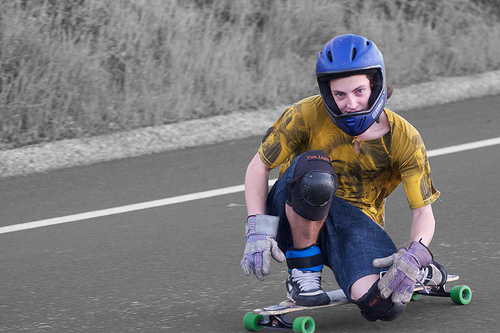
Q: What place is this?
A: It is a road.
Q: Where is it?
A: This is at the road.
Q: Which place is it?
A: It is a road.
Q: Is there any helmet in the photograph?
A: Yes, there is a helmet.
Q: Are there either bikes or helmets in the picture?
A: Yes, there is a helmet.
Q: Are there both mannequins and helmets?
A: No, there is a helmet but no mannequins.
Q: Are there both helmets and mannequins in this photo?
A: No, there is a helmet but no mannequins.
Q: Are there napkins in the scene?
A: No, there are no napkins.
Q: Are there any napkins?
A: No, there are no napkins.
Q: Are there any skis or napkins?
A: No, there are no napkins or skis.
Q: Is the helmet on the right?
A: Yes, the helmet is on the right of the image.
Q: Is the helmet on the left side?
A: No, the helmet is on the right of the image.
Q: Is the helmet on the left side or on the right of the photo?
A: The helmet is on the right of the image.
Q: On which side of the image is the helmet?
A: The helmet is on the right of the image.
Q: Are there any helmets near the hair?
A: Yes, there is a helmet near the hair.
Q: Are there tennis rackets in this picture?
A: No, there are no tennis rackets.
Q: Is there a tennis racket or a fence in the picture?
A: No, there are no rackets or fences.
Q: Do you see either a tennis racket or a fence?
A: No, there are no rackets or fences.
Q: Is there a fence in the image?
A: No, there are no fences.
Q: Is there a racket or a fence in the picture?
A: No, there are no fences or rackets.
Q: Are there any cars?
A: No, there are no cars.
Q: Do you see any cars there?
A: No, there are no cars.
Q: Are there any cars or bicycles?
A: No, there are no cars or bicycles.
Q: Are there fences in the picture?
A: No, there are no fences.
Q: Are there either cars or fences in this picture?
A: No, there are no fences or cars.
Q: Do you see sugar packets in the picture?
A: No, there are no sugar packets.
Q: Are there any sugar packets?
A: No, there are no sugar packets.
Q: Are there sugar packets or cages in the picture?
A: No, there are no sugar packets or cages.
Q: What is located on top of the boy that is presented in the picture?
A: The knee pad is on top of the boy.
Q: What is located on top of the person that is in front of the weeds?
A: The knee pad is on top of the boy.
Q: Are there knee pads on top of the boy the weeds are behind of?
A: Yes, there is a knee pad on top of the boy.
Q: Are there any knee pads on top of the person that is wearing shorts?
A: Yes, there is a knee pad on top of the boy.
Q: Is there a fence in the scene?
A: No, there are no fences.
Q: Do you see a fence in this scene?
A: No, there are no fences.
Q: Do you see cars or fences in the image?
A: No, there are no fences or cars.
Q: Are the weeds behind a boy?
A: Yes, the weeds are behind a boy.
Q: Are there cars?
A: No, there are no cars.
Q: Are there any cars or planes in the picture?
A: No, there are no cars or planes.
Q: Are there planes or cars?
A: No, there are no cars or planes.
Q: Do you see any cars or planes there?
A: No, there are no cars or planes.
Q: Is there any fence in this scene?
A: No, there are no fences.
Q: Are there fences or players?
A: No, there are no fences or players.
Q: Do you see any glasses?
A: No, there are no glasses.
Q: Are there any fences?
A: No, there are no fences.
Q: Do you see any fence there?
A: No, there are no fences.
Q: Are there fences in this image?
A: No, there are no fences.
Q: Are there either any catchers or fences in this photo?
A: No, there are no fences or catchers.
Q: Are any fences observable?
A: No, there are no fences.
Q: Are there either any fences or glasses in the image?
A: No, there are no fences or glasses.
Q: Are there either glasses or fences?
A: No, there are no fences or glasses.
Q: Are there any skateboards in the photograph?
A: Yes, there is a skateboard.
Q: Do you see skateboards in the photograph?
A: Yes, there is a skateboard.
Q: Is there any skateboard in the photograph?
A: Yes, there is a skateboard.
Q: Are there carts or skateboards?
A: Yes, there is a skateboard.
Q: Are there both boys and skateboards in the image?
A: Yes, there are both a skateboard and a boy.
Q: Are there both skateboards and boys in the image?
A: Yes, there are both a skateboard and a boy.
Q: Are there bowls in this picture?
A: No, there are no bowls.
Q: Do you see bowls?
A: No, there are no bowls.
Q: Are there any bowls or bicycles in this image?
A: No, there are no bowls or bicycles.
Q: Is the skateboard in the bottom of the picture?
A: Yes, the skateboard is in the bottom of the image.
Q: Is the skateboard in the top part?
A: No, the skateboard is in the bottom of the image.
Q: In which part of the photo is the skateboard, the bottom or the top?
A: The skateboard is in the bottom of the image.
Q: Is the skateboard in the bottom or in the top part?
A: The skateboard is in the bottom of the image.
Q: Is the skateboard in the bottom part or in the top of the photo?
A: The skateboard is in the bottom of the image.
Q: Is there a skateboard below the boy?
A: Yes, there is a skateboard below the boy.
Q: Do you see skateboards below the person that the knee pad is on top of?
A: Yes, there is a skateboard below the boy.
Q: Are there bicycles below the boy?
A: No, there is a skateboard below the boy.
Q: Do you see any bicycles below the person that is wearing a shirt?
A: No, there is a skateboard below the boy.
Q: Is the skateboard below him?
A: Yes, the skateboard is below the boy.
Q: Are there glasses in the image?
A: No, there are no glasses.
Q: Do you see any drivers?
A: No, there are no drivers.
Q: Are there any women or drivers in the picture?
A: No, there are no drivers or women.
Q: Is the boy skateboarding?
A: Yes, the boy is skateboarding.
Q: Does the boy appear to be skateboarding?
A: Yes, the boy is skateboarding.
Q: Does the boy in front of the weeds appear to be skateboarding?
A: Yes, the boy is skateboarding.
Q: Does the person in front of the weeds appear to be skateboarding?
A: Yes, the boy is skateboarding.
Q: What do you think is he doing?
A: The boy is skateboarding.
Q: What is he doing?
A: The boy is skateboarding.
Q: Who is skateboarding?
A: The boy is skateboarding.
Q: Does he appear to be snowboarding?
A: No, the boy is skateboarding.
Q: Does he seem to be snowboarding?
A: No, the boy is skateboarding.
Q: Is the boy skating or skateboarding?
A: The boy is skateboarding.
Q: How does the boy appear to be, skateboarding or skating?
A: The boy is skateboarding.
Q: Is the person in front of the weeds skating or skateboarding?
A: The boy is skateboarding.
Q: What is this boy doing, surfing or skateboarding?
A: The boy is skateboarding.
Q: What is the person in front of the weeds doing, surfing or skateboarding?
A: The boy is skateboarding.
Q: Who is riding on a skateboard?
A: The boy is riding on a skateboard.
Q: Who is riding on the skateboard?
A: The boy is riding on a skateboard.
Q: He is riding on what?
A: The boy is riding on a skateboard.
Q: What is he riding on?
A: The boy is riding on a skateboard.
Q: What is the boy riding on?
A: The boy is riding on a skateboard.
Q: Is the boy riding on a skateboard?
A: Yes, the boy is riding on a skateboard.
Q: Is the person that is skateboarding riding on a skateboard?
A: Yes, the boy is riding on a skateboard.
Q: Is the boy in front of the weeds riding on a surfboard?
A: No, the boy is riding on a skateboard.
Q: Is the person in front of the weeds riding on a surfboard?
A: No, the boy is riding on a skateboard.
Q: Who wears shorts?
A: The boy wears shorts.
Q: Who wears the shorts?
A: The boy wears shorts.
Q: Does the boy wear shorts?
A: Yes, the boy wears shorts.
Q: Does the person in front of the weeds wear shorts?
A: Yes, the boy wears shorts.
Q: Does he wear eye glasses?
A: No, the boy wears shorts.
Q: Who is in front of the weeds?
A: The boy is in front of the weeds.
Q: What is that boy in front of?
A: The boy is in front of the weeds.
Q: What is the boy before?
A: The boy is in front of the weeds.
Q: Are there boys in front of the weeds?
A: Yes, there is a boy in front of the weeds.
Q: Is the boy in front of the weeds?
A: Yes, the boy is in front of the weeds.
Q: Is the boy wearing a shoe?
A: Yes, the boy is wearing a shoe.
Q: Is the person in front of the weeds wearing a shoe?
A: Yes, the boy is wearing a shoe.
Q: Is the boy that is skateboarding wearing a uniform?
A: No, the boy is wearing a shoe.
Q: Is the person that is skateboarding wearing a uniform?
A: No, the boy is wearing a shoe.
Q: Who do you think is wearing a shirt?
A: The boy is wearing a shirt.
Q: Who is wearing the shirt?
A: The boy is wearing a shirt.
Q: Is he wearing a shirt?
A: Yes, the boy is wearing a shirt.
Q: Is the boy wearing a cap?
A: No, the boy is wearing a shirt.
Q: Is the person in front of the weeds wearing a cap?
A: No, the boy is wearing a shirt.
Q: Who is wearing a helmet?
A: The boy is wearing a helmet.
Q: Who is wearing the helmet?
A: The boy is wearing a helmet.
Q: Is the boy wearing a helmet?
A: Yes, the boy is wearing a helmet.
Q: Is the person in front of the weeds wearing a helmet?
A: Yes, the boy is wearing a helmet.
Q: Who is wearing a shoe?
A: The boy is wearing a shoe.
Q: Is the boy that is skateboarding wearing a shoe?
A: Yes, the boy is wearing a shoe.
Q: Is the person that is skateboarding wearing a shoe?
A: Yes, the boy is wearing a shoe.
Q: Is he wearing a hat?
A: No, the boy is wearing a shoe.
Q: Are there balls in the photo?
A: No, there are no balls.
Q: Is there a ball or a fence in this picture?
A: No, there are no balls or fences.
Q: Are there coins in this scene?
A: No, there are no coins.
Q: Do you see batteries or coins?
A: No, there are no coins or batteries.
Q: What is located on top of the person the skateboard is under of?
A: The knee pad is on top of the boy.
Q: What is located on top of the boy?
A: The knee pad is on top of the boy.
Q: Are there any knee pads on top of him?
A: Yes, there is a knee pad on top of the boy.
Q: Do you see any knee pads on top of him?
A: Yes, there is a knee pad on top of the boy.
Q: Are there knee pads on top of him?
A: Yes, there is a knee pad on top of the boy.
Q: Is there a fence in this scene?
A: No, there are no fences.